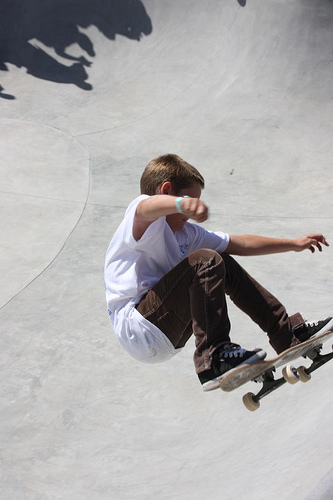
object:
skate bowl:
[0, 0, 332, 499]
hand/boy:
[177, 194, 209, 225]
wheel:
[296, 365, 312, 387]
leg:
[224, 251, 288, 342]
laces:
[218, 342, 249, 360]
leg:
[131, 248, 227, 369]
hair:
[140, 153, 204, 195]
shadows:
[0, 0, 154, 102]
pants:
[136, 245, 304, 376]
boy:
[104, 153, 331, 395]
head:
[139, 154, 206, 232]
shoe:
[198, 341, 267, 394]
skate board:
[218, 331, 332, 413]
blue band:
[175, 192, 188, 217]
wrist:
[283, 230, 305, 257]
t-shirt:
[103, 194, 230, 362]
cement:
[60, 396, 255, 485]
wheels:
[280, 365, 299, 387]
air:
[160, 20, 321, 146]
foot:
[197, 342, 267, 392]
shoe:
[268, 314, 333, 356]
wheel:
[242, 392, 259, 413]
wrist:
[166, 193, 192, 218]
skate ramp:
[0, 1, 332, 499]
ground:
[0, 0, 333, 498]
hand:
[292, 229, 330, 257]